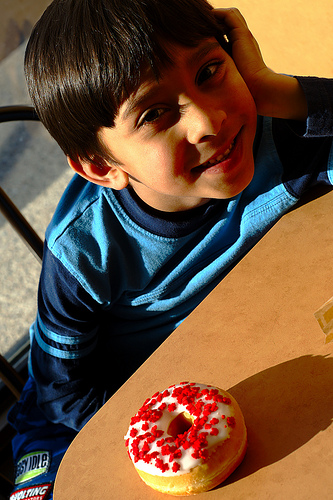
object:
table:
[52, 191, 333, 500]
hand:
[29, 244, 104, 498]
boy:
[0, 0, 333, 500]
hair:
[23, 0, 233, 168]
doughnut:
[125, 380, 248, 496]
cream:
[126, 380, 231, 477]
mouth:
[187, 123, 247, 177]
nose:
[187, 93, 228, 144]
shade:
[247, 352, 331, 459]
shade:
[183, 1, 332, 209]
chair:
[0, 106, 46, 399]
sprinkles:
[130, 380, 236, 474]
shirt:
[25, 73, 333, 430]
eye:
[132, 101, 170, 129]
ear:
[67, 147, 130, 191]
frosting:
[126, 379, 234, 467]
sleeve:
[26, 237, 112, 426]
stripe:
[34, 318, 86, 360]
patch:
[4, 483, 51, 500]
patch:
[10, 449, 48, 483]